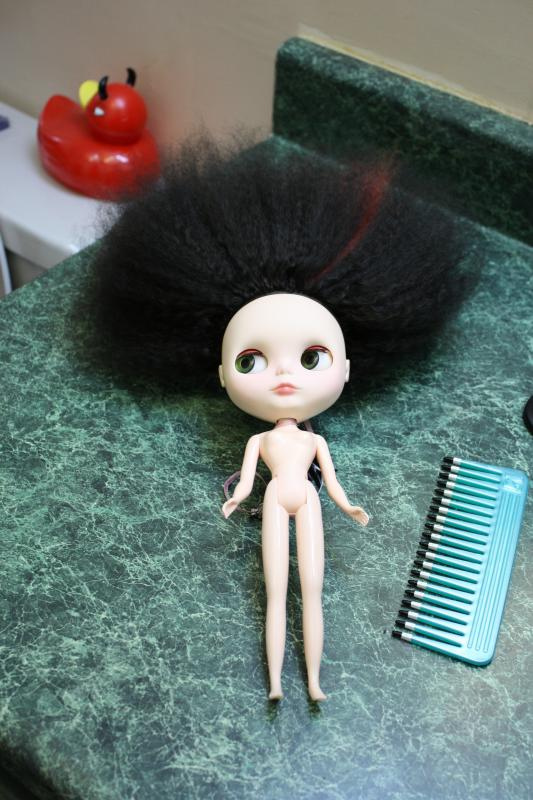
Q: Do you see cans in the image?
A: No, there are no cans.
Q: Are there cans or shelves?
A: No, there are no cans or shelves.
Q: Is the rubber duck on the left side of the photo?
A: Yes, the rubber duck is on the left of the image.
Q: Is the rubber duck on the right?
A: No, the rubber duck is on the left of the image.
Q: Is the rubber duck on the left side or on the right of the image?
A: The rubber duck is on the left of the image.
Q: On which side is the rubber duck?
A: The rubber duck is on the left of the image.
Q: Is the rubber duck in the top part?
A: Yes, the rubber duck is in the top of the image.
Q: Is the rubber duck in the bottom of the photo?
A: No, the rubber duck is in the top of the image.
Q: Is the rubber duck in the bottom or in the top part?
A: The rubber duck is in the top of the image.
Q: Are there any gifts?
A: No, there are no gifts.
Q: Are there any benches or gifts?
A: No, there are no gifts or benches.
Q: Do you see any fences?
A: No, there are no fences.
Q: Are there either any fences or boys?
A: No, there are no fences or boys.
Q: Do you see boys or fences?
A: No, there are no fences or boys.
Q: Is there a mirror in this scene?
A: No, there are no mirrors.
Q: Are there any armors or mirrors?
A: No, there are no mirrors or armors.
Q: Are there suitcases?
A: No, there are no suitcases.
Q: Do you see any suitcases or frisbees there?
A: No, there are no suitcases or frisbees.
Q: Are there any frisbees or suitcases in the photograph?
A: No, there are no suitcases or frisbees.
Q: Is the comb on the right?
A: Yes, the comb is on the right of the image.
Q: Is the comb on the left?
A: No, the comb is on the right of the image.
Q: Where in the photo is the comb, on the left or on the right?
A: The comb is on the right of the image.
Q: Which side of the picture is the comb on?
A: The comb is on the right of the image.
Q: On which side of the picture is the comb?
A: The comb is on the right of the image.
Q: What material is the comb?
A: The comb is made of plastic.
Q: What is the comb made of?
A: The comb is made of plastic.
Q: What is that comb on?
A: The comb is on the counter.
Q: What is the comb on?
A: The comb is on the counter.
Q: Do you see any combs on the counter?
A: Yes, there is a comb on the counter.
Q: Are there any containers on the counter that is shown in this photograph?
A: No, there is a comb on the counter.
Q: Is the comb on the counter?
A: Yes, the comb is on the counter.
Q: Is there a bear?
A: No, there are no bears.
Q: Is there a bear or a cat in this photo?
A: No, there are no bears or cats.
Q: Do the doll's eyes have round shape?
A: Yes, the eyes are round.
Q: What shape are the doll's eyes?
A: The eyes are round.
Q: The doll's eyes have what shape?
A: The eyes are round.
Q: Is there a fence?
A: No, there are no fences.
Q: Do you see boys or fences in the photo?
A: No, there are no fences or boys.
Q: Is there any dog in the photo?
A: No, there are no dogs.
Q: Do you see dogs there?
A: No, there are no dogs.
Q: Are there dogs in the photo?
A: No, there are no dogs.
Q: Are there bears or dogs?
A: No, there are no dogs or bears.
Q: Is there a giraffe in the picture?
A: No, there are no giraffes.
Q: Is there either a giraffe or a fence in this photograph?
A: No, there are no giraffes or fences.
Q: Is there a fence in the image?
A: No, there are no fences.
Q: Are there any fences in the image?
A: No, there are no fences.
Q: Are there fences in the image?
A: No, there are no fences.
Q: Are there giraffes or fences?
A: No, there are no fences or giraffes.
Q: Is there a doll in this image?
A: Yes, there is a doll.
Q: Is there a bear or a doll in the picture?
A: Yes, there is a doll.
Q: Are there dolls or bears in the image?
A: Yes, there is a doll.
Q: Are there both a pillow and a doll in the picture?
A: No, there is a doll but no pillows.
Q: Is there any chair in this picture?
A: No, there are no chairs.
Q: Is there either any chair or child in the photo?
A: No, there are no chairs or children.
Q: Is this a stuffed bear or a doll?
A: This is a doll.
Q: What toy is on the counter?
A: The toy is a doll.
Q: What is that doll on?
A: The doll is on the counter.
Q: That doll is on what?
A: The doll is on the counter.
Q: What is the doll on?
A: The doll is on the counter.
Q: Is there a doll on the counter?
A: Yes, there is a doll on the counter.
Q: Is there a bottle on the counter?
A: No, there is a doll on the counter.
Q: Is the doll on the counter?
A: Yes, the doll is on the counter.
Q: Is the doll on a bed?
A: No, the doll is on the counter.